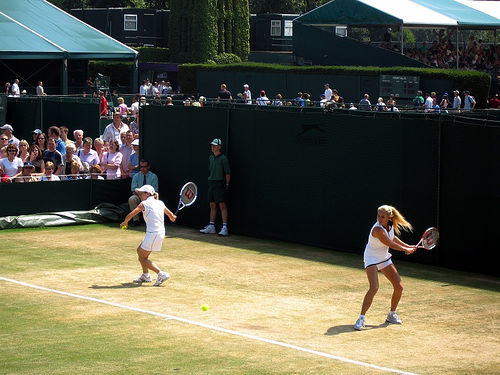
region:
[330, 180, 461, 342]
woman playing tennis on court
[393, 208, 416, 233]
brown hair waving in wind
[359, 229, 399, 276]
white tennis top on woman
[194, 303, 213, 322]
yellow tennis ball in air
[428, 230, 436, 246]
red logo on racket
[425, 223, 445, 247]
red and white racket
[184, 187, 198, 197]
red logo on racket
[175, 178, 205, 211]
red and white racket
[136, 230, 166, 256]
white tennis shorts on woman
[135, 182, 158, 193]
white hat on head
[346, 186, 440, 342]
woman playing tennis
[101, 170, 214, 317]
woman playing tennis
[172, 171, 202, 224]
recket with a red W on it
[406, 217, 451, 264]
racket in a woman's hand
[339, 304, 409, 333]
white shoes on a tennis player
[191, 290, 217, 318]
yellow ball in the air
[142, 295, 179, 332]
white line on the court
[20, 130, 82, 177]
spectators on the sidelines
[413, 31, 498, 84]
people in the stands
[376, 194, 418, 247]
long hair on a woman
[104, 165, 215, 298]
woman playing tennis on tennis court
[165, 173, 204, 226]
tennis racket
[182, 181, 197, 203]
tennis racket brand name on tennis netting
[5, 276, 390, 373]
white line drawn on tennis court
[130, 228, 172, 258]
white tennis skirt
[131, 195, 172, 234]
short sleeve white shirt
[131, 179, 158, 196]
tennis hat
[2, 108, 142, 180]
tennis spectators behind green tarp fence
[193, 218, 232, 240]
pair of white sneakers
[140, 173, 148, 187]
tie around man's neck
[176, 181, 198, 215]
blue metal tennis racquet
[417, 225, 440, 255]
red and white tennis racquet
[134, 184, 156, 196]
white cap on head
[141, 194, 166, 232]
white cotton sleeveless shirt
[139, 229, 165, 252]
white cotton tennis skirt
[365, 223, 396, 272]
white cotton tennis dress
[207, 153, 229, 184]
green cotton polo shirt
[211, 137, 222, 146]
white cap on head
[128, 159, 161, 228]
man sitting on chair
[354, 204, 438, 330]
girl holding tennis racquet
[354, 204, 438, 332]
woman holding a tennis racket with both hand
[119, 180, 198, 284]
woman holding a tennis racket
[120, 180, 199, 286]
woman wearing a white cap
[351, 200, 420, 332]
girl with ponytail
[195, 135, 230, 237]
man standing on tennis court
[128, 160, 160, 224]
man wearing a tie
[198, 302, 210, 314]
tennis ball in mid-air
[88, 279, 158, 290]
woman's shadow on tennis court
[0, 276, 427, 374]
white line on the court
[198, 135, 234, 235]
man wearing dark short